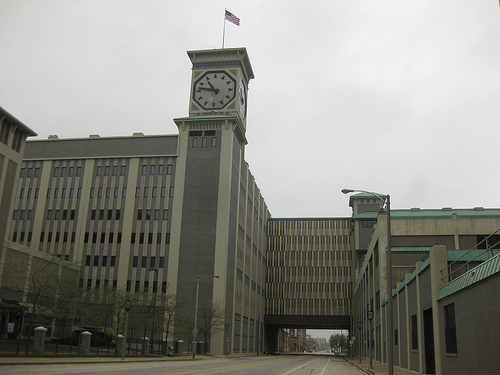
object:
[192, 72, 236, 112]
face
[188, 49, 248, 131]
clock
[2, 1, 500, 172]
sky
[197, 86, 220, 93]
hand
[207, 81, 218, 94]
hand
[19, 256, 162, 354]
trees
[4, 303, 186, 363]
courtyard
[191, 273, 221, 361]
street light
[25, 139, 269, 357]
building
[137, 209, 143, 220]
window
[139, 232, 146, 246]
window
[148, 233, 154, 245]
window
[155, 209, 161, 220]
window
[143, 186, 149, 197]
window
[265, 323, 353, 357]
an underpass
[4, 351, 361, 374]
road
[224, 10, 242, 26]
american flag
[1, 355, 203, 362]
sidewalk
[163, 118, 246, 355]
tower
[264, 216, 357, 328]
bridge walkway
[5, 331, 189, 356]
fence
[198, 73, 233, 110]
numbers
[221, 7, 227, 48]
pole